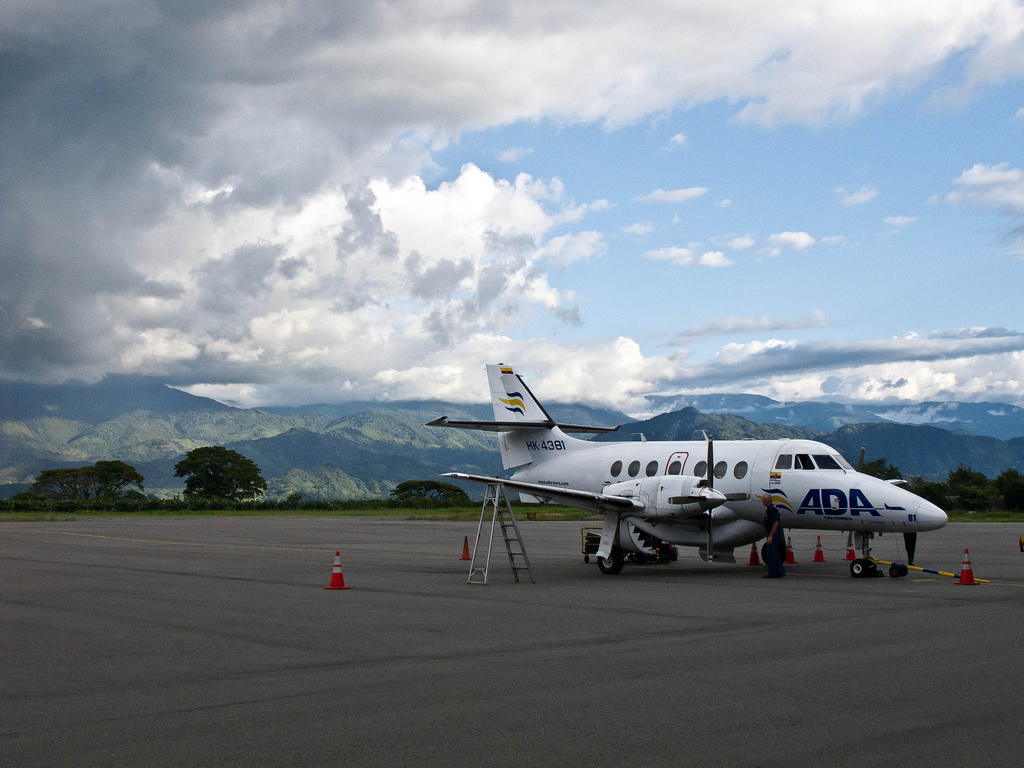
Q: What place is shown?
A: It is a pavement.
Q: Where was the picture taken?
A: It was taken at the pavement.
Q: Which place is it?
A: It is a pavement.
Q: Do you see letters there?
A: Yes, there are letters.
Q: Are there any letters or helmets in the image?
A: Yes, there are letters.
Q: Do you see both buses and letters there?
A: No, there are letters but no buses.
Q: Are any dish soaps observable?
A: No, there are no dish soaps.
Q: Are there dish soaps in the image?
A: No, there are no dish soaps.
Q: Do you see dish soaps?
A: No, there are no dish soaps.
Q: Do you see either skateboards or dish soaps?
A: No, there are no dish soaps or skateboards.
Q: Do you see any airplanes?
A: Yes, there is an airplane.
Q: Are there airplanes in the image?
A: Yes, there is an airplane.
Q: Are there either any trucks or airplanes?
A: Yes, there is an airplane.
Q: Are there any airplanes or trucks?
A: Yes, there is an airplane.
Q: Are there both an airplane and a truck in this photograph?
A: No, there is an airplane but no trucks.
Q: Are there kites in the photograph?
A: No, there are no kites.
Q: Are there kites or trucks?
A: No, there are no kites or trucks.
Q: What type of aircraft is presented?
A: The aircraft is an airplane.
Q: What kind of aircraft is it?
A: The aircraft is an airplane.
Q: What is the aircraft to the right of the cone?
A: The aircraft is an airplane.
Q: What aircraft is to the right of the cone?
A: The aircraft is an airplane.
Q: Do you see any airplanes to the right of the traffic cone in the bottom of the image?
A: Yes, there is an airplane to the right of the cone.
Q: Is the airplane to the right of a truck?
A: No, the airplane is to the right of the traffic cone.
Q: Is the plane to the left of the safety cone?
A: No, the plane is to the right of the safety cone.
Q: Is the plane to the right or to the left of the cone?
A: The plane is to the right of the cone.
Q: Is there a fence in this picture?
A: No, there are no fences.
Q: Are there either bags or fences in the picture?
A: No, there are no fences or bags.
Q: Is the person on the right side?
A: Yes, the person is on the right of the image.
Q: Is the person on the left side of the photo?
A: No, the person is on the right of the image.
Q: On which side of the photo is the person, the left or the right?
A: The person is on the right of the image.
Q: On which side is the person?
A: The person is on the right of the image.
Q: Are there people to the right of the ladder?
A: Yes, there is a person to the right of the ladder.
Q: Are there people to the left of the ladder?
A: No, the person is to the right of the ladder.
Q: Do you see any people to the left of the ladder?
A: No, the person is to the right of the ladder.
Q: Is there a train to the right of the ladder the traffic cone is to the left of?
A: No, there is a person to the right of the ladder.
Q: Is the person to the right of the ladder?
A: Yes, the person is to the right of the ladder.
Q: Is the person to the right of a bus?
A: No, the person is to the right of the ladder.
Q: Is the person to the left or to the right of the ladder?
A: The person is to the right of the ladder.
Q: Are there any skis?
A: No, there are no skis.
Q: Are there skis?
A: No, there are no skis.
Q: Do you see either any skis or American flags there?
A: No, there are no skis or American flags.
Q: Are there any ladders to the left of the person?
A: Yes, there is a ladder to the left of the person.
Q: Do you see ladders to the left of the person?
A: Yes, there is a ladder to the left of the person.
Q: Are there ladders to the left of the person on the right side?
A: Yes, there is a ladder to the left of the person.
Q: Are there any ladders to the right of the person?
A: No, the ladder is to the left of the person.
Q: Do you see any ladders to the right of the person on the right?
A: No, the ladder is to the left of the person.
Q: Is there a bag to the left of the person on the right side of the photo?
A: No, there is a ladder to the left of the person.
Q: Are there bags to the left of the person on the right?
A: No, there is a ladder to the left of the person.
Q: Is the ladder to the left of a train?
A: No, the ladder is to the left of the person.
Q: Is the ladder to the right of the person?
A: No, the ladder is to the left of the person.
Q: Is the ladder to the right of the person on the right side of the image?
A: No, the ladder is to the left of the person.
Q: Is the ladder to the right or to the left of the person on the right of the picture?
A: The ladder is to the left of the person.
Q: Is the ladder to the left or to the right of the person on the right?
A: The ladder is to the left of the person.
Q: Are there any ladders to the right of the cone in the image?
A: Yes, there is a ladder to the right of the cone.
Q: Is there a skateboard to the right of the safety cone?
A: No, there is a ladder to the right of the safety cone.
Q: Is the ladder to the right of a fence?
A: No, the ladder is to the right of the traffic cone.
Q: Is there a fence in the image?
A: No, there are no fences.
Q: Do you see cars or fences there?
A: No, there are no fences or cars.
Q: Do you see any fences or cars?
A: No, there are no fences or cars.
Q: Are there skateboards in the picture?
A: No, there are no skateboards.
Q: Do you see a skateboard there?
A: No, there are no skateboards.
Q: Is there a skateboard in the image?
A: No, there are no skateboards.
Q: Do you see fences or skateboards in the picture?
A: No, there are no skateboards or fences.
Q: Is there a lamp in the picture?
A: No, there are no lamps.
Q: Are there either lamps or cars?
A: No, there are no lamps or cars.